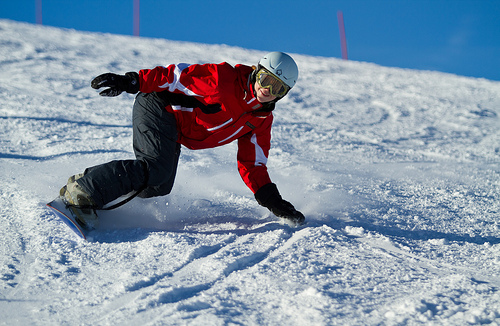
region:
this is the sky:
[385, 12, 485, 34]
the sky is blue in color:
[406, 20, 458, 42]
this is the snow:
[328, 173, 427, 223]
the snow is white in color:
[347, 143, 485, 263]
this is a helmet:
[256, 50, 309, 74]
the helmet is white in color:
[263, 52, 302, 71]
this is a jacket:
[186, 78, 246, 135]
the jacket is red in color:
[193, 80, 239, 130]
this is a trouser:
[126, 108, 170, 168]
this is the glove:
[106, 65, 131, 88]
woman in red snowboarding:
[96, 36, 362, 265]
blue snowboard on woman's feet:
[41, 195, 119, 260]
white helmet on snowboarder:
[232, 30, 315, 87]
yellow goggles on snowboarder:
[258, 70, 291, 101]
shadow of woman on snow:
[239, 172, 484, 301]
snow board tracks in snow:
[51, 245, 193, 323]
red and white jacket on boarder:
[161, 61, 260, 180]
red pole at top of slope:
[329, 7, 375, 68]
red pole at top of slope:
[124, 1, 154, 38]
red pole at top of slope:
[15, 3, 48, 41]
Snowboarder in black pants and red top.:
[46, 50, 304, 235]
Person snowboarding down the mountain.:
[48, 50, 305, 222]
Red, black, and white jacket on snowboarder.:
[138, 61, 275, 193]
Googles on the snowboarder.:
[256, 70, 288, 95]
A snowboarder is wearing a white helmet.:
[257, 50, 299, 88]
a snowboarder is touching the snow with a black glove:
[253, 182, 305, 224]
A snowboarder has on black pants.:
[81, 93, 180, 208]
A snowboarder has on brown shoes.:
[61, 173, 98, 220]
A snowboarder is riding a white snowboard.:
[46, 195, 86, 240]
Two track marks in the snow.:
[123, 217, 293, 307]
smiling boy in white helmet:
[241, 45, 313, 132]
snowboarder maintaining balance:
[51, 46, 323, 246]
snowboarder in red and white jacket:
[42, 46, 319, 259]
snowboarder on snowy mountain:
[27, 45, 328, 252]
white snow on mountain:
[352, 100, 451, 238]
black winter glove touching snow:
[231, 173, 332, 237]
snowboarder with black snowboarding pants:
[46, 35, 318, 255]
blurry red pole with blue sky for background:
[325, 8, 370, 68]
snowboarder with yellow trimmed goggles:
[252, 57, 301, 112]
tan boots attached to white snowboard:
[37, 165, 115, 253]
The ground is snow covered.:
[12, 33, 499, 310]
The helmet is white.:
[254, 41, 309, 84]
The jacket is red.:
[133, 57, 284, 199]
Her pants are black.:
[72, 93, 187, 224]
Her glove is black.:
[93, 65, 143, 102]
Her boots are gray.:
[60, 173, 100, 220]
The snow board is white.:
[43, 180, 94, 240]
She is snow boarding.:
[43, 35, 321, 252]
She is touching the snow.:
[219, 188, 336, 250]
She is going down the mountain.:
[35, 20, 495, 309]